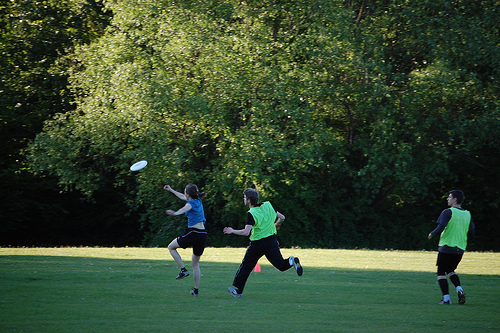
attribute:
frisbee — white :
[107, 142, 165, 186]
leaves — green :
[326, 98, 365, 154]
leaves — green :
[160, 32, 268, 110]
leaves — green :
[274, 52, 457, 234]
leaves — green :
[257, 63, 287, 116]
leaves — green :
[364, 51, 402, 141]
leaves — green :
[244, 60, 311, 167]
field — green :
[15, 167, 470, 324]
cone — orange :
[234, 248, 284, 301]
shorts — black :
[154, 199, 245, 267]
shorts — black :
[236, 242, 328, 295]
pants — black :
[228, 248, 311, 298]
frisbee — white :
[123, 124, 153, 194]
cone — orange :
[251, 249, 277, 288]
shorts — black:
[170, 240, 218, 250]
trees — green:
[121, 66, 326, 186]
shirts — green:
[265, 212, 452, 266]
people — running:
[165, 180, 455, 276]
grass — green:
[324, 254, 376, 310]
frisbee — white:
[102, 152, 161, 182]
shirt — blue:
[167, 185, 223, 237]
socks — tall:
[429, 270, 485, 313]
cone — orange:
[248, 256, 267, 278]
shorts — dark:
[173, 220, 191, 245]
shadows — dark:
[41, 185, 145, 288]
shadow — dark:
[308, 273, 357, 318]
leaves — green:
[193, 55, 354, 196]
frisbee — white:
[116, 150, 156, 180]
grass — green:
[310, 223, 370, 316]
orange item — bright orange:
[253, 261, 264, 273]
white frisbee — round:
[128, 158, 147, 170]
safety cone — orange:
[251, 263, 265, 271]